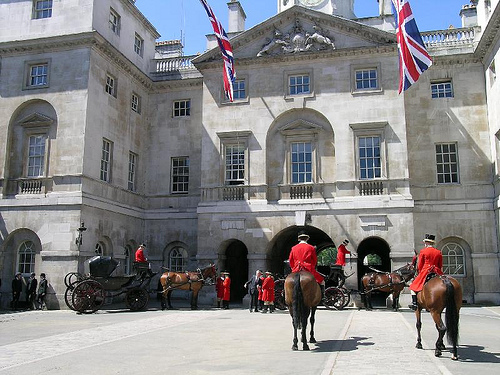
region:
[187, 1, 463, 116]
two British flags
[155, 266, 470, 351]
four brown horses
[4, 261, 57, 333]
three men talking about different topics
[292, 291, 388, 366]
the shadow of the horse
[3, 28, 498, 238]
an impressive building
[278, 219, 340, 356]
a man riding a horse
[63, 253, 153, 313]
a beatiful charcoal carriage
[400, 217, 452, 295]
a man in a red shirt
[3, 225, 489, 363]
eleven people doing different things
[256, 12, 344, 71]
a symbolic figure at the top of the building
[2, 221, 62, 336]
A group of people talking outside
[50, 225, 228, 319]
A horse drawn carriage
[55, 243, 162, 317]
A black carriage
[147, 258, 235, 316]
A large horse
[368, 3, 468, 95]
The union flag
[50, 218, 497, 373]
A group of riders on horse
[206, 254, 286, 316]
People in red uniforms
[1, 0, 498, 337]
A large brick building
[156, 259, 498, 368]
Many black and brown horses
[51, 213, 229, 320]
A man driving a horse drawn carriage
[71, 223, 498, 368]
Brown horses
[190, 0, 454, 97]
Red, white and blue flag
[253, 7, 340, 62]
Statute on building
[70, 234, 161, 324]
Black horse buggy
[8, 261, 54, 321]
Three people sitting on side of building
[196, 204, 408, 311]
Building have three arches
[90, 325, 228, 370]
Gray pavement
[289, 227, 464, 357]
Three riders riding brown horses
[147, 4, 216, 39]
Blue clear sunny sky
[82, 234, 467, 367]
Seven people with red jackets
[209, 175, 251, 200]
open window in the courtyard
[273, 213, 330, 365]
man in red on a horse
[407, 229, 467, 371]
man in red on a horse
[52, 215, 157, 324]
man in red driving a buggy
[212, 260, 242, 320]
men in red suits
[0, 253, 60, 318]
three men standing by a wall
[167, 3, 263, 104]
British flags flying in court yard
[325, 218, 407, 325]
man controlling a horse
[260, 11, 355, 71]
lions etched in the stone of the house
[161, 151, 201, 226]
open window in the building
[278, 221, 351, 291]
Rider in a red coat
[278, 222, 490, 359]
The horses are standing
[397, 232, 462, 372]
The horse is a bay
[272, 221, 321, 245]
The riders hat is black and yellow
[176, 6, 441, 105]
Blue, red, and white flags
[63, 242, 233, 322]
The carriage is black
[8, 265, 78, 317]
People standing by the building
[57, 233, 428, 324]
The carriages are in front of the building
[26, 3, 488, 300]
Large three story building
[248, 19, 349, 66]
Statue on front of building